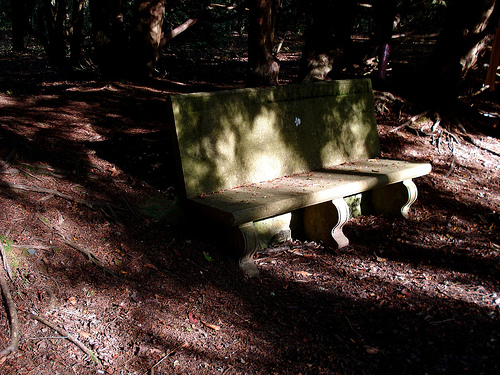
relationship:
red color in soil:
[1, 81, 176, 372] [0, 251, 500, 373]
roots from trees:
[400, 88, 499, 159] [0, 1, 499, 77]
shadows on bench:
[171, 75, 434, 250] [0, 0, 499, 373]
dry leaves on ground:
[0, 251, 500, 373] [1, 81, 176, 372]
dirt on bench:
[188, 146, 431, 225] [0, 0, 499, 373]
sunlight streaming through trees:
[0, 0, 499, 373] [0, 1, 499, 77]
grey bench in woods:
[171, 75, 434, 250] [0, 0, 499, 373]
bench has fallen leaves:
[171, 75, 434, 250] [188, 146, 431, 225]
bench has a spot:
[171, 75, 434, 250] [293, 114, 304, 128]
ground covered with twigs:
[1, 81, 176, 372] [149, 345, 178, 374]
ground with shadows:
[1, 81, 176, 372] [0, 1, 499, 374]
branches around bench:
[0, 1, 499, 77] [171, 75, 434, 250]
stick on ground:
[265, 242, 323, 262] [1, 81, 176, 372]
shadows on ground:
[0, 1, 499, 374] [1, 81, 176, 372]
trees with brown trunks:
[0, 1, 499, 77] [131, 0, 287, 87]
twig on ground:
[149, 345, 178, 374] [1, 81, 176, 372]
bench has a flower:
[171, 75, 434, 250] [293, 114, 304, 128]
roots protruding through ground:
[0, 258, 17, 363] [1, 81, 176, 372]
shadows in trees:
[0, 1, 499, 374] [0, 1, 499, 77]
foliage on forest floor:
[2, 42, 173, 195] [375, 1, 499, 155]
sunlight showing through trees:
[0, 0, 499, 373] [0, 1, 499, 77]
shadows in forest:
[0, 1, 499, 374] [0, 0, 499, 373]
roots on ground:
[0, 258, 17, 363] [1, 81, 176, 372]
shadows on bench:
[0, 1, 499, 374] [171, 75, 434, 250]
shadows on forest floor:
[0, 1, 499, 374] [0, 0, 499, 373]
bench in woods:
[171, 75, 434, 250] [0, 0, 499, 373]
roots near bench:
[400, 88, 499, 159] [171, 75, 434, 250]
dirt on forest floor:
[1, 81, 176, 372] [1, 1, 169, 375]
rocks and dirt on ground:
[379, 85, 499, 162] [1, 81, 176, 372]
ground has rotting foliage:
[1, 81, 176, 372] [1, 1, 169, 375]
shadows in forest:
[0, 1, 499, 374] [0, 1, 499, 77]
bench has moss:
[171, 75, 432, 278] [172, 76, 378, 196]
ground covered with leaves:
[1, 81, 176, 372] [1, 81, 176, 372]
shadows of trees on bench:
[171, 75, 434, 250] [163, 77, 433, 281]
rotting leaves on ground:
[1, 81, 176, 372] [1, 81, 176, 372]